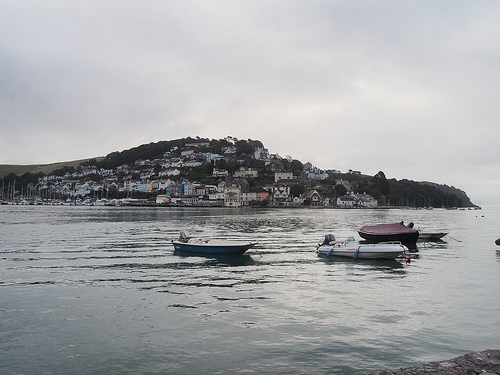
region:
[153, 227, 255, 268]
boat on water is blue and white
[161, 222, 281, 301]
boat on water is blue and white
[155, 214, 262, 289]
the boat is floating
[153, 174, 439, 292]
there are three boats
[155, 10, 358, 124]
the sky is white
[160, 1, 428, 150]
the sky is cloudy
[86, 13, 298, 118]
the clouds are white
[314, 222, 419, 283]
the boat is white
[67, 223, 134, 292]
the water has ripples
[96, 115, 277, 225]
there are many houses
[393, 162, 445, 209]
the trees are green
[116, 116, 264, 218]
the hill is tall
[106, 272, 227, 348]
the water is rippled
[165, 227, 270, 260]
The boat on the left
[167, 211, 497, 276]
The group of boats near each other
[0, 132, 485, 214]
The hill in the background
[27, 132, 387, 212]
The houses on the hill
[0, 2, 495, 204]
The clouds above the hill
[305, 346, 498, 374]
The shore nearest the camera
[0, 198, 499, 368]
The water that the boats are on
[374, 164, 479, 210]
The end of the hill with no houses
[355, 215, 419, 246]
The boat with the cover on it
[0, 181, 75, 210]
The sail boats across the way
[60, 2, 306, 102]
this is the sky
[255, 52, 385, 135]
the sky has clouds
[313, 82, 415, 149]
the clouds are white in color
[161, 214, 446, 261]
these are boats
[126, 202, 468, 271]
the boats are floating in water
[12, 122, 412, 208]
this is an island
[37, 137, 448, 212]
the island has houses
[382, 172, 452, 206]
this is a forest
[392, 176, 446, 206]
the forest is green in color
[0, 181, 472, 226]
this is a harbor